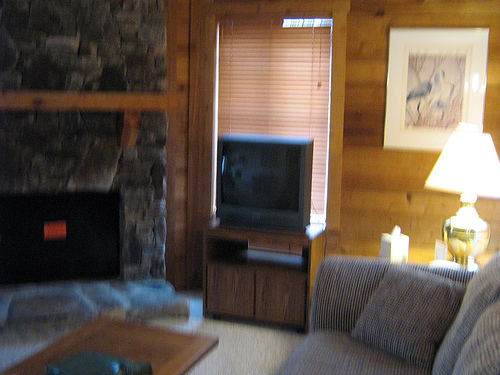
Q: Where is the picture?
A: On wall.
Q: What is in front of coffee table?
A: Fireplace.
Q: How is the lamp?
A: On.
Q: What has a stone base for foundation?
A: Fireplace.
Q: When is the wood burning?
A: Fireplace is lit.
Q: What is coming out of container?
A: Tissue.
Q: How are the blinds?
A: Closed.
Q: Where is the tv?
A: On stand.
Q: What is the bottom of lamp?
A: Gold.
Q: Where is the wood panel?
A: On wall.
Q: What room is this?
A: Living room.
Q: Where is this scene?
A: House.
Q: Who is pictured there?
A: No person.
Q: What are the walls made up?
A: Wood.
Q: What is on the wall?
A: Picture.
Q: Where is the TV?
A: Middle.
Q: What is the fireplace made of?
A: Stone.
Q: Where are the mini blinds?
A: Behind TV.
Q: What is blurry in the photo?
A: Everything.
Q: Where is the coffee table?
A: In front of sofa.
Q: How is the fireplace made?
A: With stones.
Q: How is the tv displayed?
A: On tv stand center.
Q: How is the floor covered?
A: With carpet.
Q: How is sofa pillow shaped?
A: Square.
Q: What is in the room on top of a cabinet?
A: A television.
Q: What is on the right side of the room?
A: A grey striped couch.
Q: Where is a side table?
A: Between couch and wall.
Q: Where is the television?
A: Sitting on tv stand.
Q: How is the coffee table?
A: It is brown and wooden.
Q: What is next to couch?
A: Table lamp.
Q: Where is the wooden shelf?
A: Above the fireplace.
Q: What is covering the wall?
A: Wood panelling.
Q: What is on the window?
A: Brown blinds.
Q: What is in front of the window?
A: A TV.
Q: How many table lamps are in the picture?
A: One.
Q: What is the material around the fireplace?
A: Flagstone.